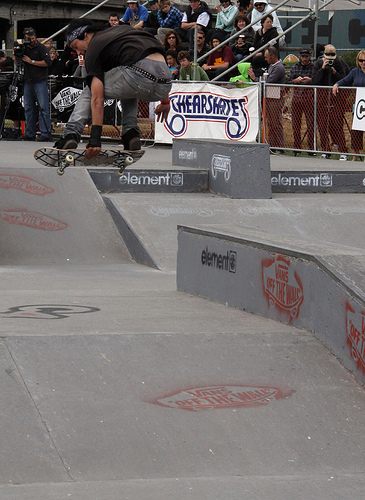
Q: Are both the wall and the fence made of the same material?
A: No, the wall is made of concrete and the fence is made of metal.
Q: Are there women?
A: Yes, there is a woman.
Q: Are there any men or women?
A: Yes, there is a woman.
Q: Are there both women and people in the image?
A: Yes, there are both a woman and a person.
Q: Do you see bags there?
A: No, there are no bags.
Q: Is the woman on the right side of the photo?
A: Yes, the woman is on the right of the image.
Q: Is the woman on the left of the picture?
A: No, the woman is on the right of the image.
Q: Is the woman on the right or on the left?
A: The woman is on the right of the image.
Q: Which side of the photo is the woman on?
A: The woman is on the right of the image.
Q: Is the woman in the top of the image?
A: Yes, the woman is in the top of the image.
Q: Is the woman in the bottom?
A: No, the woman is in the top of the image.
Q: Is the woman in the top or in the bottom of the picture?
A: The woman is in the top of the image.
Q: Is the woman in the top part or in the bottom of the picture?
A: The woman is in the top of the image.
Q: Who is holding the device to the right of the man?
A: The woman is holding the camera.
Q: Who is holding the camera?
A: The woman is holding the camera.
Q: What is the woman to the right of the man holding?
A: The woman is holding the camera.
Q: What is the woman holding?
A: The woman is holding the camera.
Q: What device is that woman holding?
A: The woman is holding the camera.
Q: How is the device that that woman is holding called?
A: The device is a camera.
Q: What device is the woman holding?
A: The woman is holding the camera.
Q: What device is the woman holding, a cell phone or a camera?
A: The woman is holding a camera.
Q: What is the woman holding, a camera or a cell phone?
A: The woman is holding a camera.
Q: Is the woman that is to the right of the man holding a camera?
A: Yes, the woman is holding a camera.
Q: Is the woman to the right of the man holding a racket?
A: No, the woman is holding a camera.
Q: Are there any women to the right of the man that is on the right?
A: Yes, there is a woman to the right of the man.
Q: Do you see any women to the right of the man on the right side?
A: Yes, there is a woman to the right of the man.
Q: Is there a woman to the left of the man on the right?
A: No, the woman is to the right of the man.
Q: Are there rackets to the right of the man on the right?
A: No, there is a woman to the right of the man.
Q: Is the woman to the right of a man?
A: Yes, the woman is to the right of a man.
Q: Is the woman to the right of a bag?
A: No, the woman is to the right of a man.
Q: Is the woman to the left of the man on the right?
A: No, the woman is to the right of the man.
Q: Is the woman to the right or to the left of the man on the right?
A: The woman is to the right of the man.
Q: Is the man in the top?
A: Yes, the man is in the top of the image.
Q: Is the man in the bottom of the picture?
A: No, the man is in the top of the image.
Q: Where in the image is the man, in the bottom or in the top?
A: The man is in the top of the image.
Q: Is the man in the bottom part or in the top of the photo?
A: The man is in the top of the image.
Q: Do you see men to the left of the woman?
A: Yes, there is a man to the left of the woman.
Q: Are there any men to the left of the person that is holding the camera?
A: Yes, there is a man to the left of the woman.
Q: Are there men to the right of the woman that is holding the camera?
A: No, the man is to the left of the woman.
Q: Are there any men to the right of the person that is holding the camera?
A: No, the man is to the left of the woman.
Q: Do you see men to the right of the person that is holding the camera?
A: No, the man is to the left of the woman.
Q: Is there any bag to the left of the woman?
A: No, there is a man to the left of the woman.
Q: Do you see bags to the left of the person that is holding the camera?
A: No, there is a man to the left of the woman.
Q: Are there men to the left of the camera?
A: Yes, there is a man to the left of the camera.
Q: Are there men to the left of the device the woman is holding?
A: Yes, there is a man to the left of the camera.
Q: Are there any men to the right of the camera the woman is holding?
A: No, the man is to the left of the camera.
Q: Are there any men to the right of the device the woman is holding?
A: No, the man is to the left of the camera.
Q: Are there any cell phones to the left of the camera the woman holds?
A: No, there is a man to the left of the camera.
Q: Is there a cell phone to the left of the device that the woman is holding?
A: No, there is a man to the left of the camera.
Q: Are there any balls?
A: No, there are no balls.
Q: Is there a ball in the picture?
A: No, there are no balls.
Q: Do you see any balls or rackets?
A: No, there are no balls or rackets.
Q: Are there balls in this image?
A: No, there are no balls.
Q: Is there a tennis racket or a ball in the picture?
A: No, there are no balls or rackets.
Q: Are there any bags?
A: No, there are no bags.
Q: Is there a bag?
A: No, there are no bags.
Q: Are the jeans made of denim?
A: Yes, the jeans are made of denim.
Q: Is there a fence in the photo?
A: Yes, there is a fence.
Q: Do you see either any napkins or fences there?
A: Yes, there is a fence.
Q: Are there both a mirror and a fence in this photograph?
A: No, there is a fence but no mirrors.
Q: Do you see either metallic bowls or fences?
A: Yes, there is a metal fence.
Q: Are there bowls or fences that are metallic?
A: Yes, the fence is metallic.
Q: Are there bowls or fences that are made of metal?
A: Yes, the fence is made of metal.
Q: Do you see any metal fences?
A: Yes, there is a metal fence.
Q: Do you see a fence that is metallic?
A: Yes, there is a fence that is metallic.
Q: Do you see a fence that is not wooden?
A: Yes, there is a metallic fence.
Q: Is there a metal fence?
A: Yes, there is a fence that is made of metal.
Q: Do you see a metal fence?
A: Yes, there is a fence that is made of metal.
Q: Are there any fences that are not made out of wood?
A: Yes, there is a fence that is made of metal.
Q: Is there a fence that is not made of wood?
A: Yes, there is a fence that is made of metal.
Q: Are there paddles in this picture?
A: No, there are no paddles.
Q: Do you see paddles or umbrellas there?
A: No, there are no paddles or umbrellas.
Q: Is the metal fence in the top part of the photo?
A: Yes, the fence is in the top of the image.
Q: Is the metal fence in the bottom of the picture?
A: No, the fence is in the top of the image.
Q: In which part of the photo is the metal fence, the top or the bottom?
A: The fence is in the top of the image.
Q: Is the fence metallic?
A: Yes, the fence is metallic.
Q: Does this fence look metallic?
A: Yes, the fence is metallic.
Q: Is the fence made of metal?
A: Yes, the fence is made of metal.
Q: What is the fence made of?
A: The fence is made of metal.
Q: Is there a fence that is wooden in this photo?
A: No, there is a fence but it is metallic.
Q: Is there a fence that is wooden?
A: No, there is a fence but it is metallic.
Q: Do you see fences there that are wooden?
A: No, there is a fence but it is metallic.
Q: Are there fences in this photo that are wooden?
A: No, there is a fence but it is metallic.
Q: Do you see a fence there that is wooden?
A: No, there is a fence but it is metallic.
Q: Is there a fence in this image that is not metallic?
A: No, there is a fence but it is metallic.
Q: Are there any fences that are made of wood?
A: No, there is a fence but it is made of metal.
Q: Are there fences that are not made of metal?
A: No, there is a fence but it is made of metal.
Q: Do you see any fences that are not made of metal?
A: No, there is a fence but it is made of metal.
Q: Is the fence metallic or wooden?
A: The fence is metallic.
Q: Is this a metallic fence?
A: Yes, this is a metallic fence.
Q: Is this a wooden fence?
A: No, this is a metallic fence.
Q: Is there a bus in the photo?
A: No, there are no buses.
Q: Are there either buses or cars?
A: No, there are no buses or cars.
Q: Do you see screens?
A: No, there are no screens.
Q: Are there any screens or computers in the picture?
A: No, there are no screens or computers.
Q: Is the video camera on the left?
A: Yes, the video camera is on the left of the image.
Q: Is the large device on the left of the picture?
A: Yes, the video camera is on the left of the image.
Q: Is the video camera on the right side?
A: No, the video camera is on the left of the image.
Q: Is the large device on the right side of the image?
A: No, the video camera is on the left of the image.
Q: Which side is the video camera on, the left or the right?
A: The video camera is on the left of the image.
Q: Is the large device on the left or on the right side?
A: The video camera is on the left of the image.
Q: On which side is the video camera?
A: The video camera is on the left of the image.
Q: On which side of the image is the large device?
A: The video camera is on the left of the image.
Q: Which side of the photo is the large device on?
A: The video camera is on the left of the image.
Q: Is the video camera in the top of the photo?
A: Yes, the video camera is in the top of the image.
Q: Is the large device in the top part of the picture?
A: Yes, the video camera is in the top of the image.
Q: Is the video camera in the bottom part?
A: No, the video camera is in the top of the image.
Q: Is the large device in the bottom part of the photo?
A: No, the video camera is in the top of the image.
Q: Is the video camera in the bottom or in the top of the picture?
A: The video camera is in the top of the image.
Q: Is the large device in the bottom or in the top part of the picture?
A: The video camera is in the top of the image.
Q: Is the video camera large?
A: Yes, the video camera is large.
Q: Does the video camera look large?
A: Yes, the video camera is large.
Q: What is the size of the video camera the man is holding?
A: The video camera is large.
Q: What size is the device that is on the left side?
A: The video camera is large.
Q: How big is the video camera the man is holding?
A: The video camera is large.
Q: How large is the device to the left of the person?
A: The video camera is large.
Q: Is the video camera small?
A: No, the video camera is large.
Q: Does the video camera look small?
A: No, the video camera is large.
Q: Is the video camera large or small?
A: The video camera is large.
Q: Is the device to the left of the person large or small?
A: The video camera is large.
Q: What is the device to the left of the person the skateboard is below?
A: The device is a video camera.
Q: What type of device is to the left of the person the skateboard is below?
A: The device is a video camera.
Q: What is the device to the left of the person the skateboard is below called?
A: The device is a video camera.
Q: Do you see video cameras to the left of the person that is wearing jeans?
A: Yes, there is a video camera to the left of the person.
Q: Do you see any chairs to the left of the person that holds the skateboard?
A: No, there is a video camera to the left of the person.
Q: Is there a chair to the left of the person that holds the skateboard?
A: No, there is a video camera to the left of the person.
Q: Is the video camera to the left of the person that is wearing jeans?
A: Yes, the video camera is to the left of the person.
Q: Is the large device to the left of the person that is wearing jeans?
A: Yes, the video camera is to the left of the person.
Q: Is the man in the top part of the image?
A: Yes, the man is in the top of the image.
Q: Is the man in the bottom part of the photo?
A: No, the man is in the top of the image.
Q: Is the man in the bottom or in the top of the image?
A: The man is in the top of the image.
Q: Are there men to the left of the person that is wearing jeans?
A: Yes, there is a man to the left of the person.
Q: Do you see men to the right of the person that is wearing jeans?
A: No, the man is to the left of the person.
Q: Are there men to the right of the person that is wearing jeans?
A: No, the man is to the left of the person.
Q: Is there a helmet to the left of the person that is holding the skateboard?
A: No, there is a man to the left of the person.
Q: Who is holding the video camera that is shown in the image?
A: The man is holding the video camera.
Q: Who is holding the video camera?
A: The man is holding the video camera.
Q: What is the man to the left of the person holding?
A: The man is holding the video camera.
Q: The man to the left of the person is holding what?
A: The man is holding the video camera.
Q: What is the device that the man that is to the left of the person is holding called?
A: The device is a video camera.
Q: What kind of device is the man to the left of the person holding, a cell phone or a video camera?
A: The man is holding a video camera.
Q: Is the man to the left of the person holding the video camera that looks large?
A: Yes, the man is holding the video camera.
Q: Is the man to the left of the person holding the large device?
A: Yes, the man is holding the video camera.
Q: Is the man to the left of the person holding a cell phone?
A: No, the man is holding the video camera.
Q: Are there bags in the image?
A: No, there are no bags.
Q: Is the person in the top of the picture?
A: Yes, the person is in the top of the image.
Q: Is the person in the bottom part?
A: No, the person is in the top of the image.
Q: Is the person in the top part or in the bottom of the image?
A: The person is in the top of the image.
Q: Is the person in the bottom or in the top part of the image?
A: The person is in the top of the image.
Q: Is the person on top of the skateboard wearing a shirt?
A: Yes, the person is wearing a shirt.